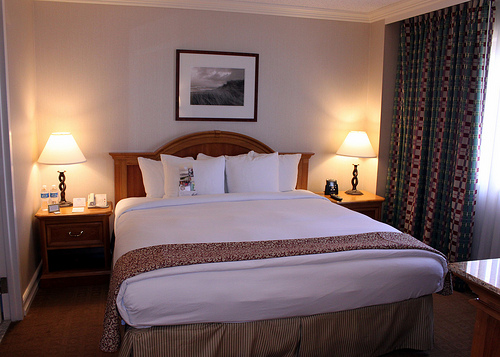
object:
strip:
[101, 232, 453, 354]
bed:
[102, 131, 449, 357]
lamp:
[37, 129, 87, 208]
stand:
[32, 202, 113, 281]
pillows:
[137, 150, 302, 198]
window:
[377, 3, 500, 205]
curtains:
[384, 1, 499, 265]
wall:
[3, 1, 371, 302]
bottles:
[40, 185, 59, 211]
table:
[333, 190, 385, 221]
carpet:
[3, 279, 99, 354]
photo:
[175, 48, 261, 123]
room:
[0, 1, 498, 356]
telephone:
[324, 179, 338, 195]